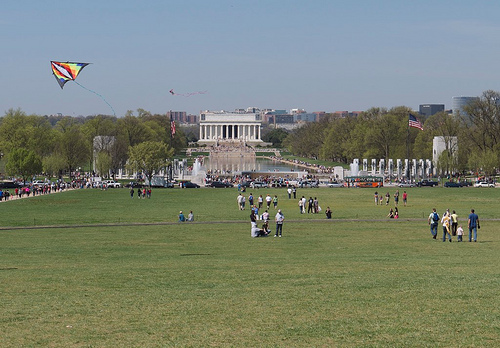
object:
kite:
[47, 58, 92, 92]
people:
[272, 207, 287, 239]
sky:
[0, 1, 500, 112]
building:
[192, 109, 269, 145]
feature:
[352, 157, 444, 178]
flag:
[406, 109, 428, 131]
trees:
[42, 150, 72, 180]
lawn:
[0, 186, 500, 347]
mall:
[0, 185, 500, 348]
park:
[0, 107, 500, 346]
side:
[68, 122, 173, 183]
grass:
[0, 187, 500, 347]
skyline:
[1, 89, 500, 121]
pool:
[258, 155, 302, 175]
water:
[261, 159, 289, 174]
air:
[108, 23, 163, 60]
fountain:
[351, 157, 437, 185]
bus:
[105, 180, 123, 189]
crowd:
[426, 206, 481, 242]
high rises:
[418, 103, 451, 124]